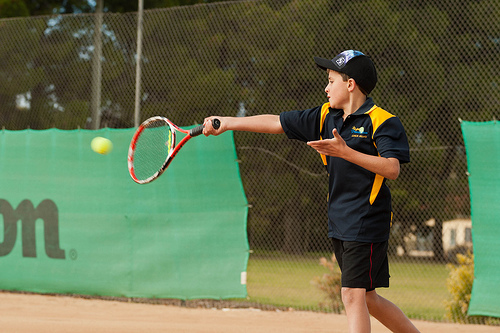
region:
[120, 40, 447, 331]
The boy plays tennis.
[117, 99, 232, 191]
The boy holds a racquet.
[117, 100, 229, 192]
The racquet is red.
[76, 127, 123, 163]
The ball is airborne.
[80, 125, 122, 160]
The ball is yellow.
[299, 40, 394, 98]
The boy wears a cap.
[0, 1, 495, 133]
A chain link fence is behind the court.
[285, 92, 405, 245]
The boy's shirt is yellow and blue.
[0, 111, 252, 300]
A green material is attached to the fence.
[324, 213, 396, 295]
The boy wears black shorts.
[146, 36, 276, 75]
green fence in the background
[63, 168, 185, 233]
green sign on fence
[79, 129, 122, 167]
yellow ball flying in the air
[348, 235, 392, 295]
red stripe on black shorts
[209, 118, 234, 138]
black edge of tennis racket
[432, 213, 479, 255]
white house peeking out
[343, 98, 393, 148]
yellow color on shirt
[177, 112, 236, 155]
black handle on racket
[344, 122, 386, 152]
word on black shirt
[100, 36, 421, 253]
boy hitting the racket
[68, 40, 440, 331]
a boy playing tennis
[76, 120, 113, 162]
a yellow tennis ball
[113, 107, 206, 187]
a red tennis racket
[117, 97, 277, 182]
boy holding a tennis racket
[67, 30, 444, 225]
boy about to hit a tennis ball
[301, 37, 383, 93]
boy wearing a black cap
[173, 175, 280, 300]
green tarp on a metal fence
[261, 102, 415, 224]
boy wearing a dark blue and yellow shirt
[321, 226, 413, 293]
black shorts with a red line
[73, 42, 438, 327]
boy playing tennis in a tennis court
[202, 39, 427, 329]
a young boy on court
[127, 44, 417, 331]
a young boy swinging tennis racket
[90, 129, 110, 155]
a yellow tennis ball in flight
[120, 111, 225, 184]
a red and black tennis racket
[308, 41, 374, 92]
a dark blue hat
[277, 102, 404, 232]
a dark blue and yellow shirt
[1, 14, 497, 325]
a chain link fence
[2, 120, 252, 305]
a long green promotional banner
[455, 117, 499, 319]
a long green promotional banner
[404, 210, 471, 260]
a building in distance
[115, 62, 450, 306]
Boy playing tennis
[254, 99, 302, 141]
Elbow is straight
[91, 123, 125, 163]
Green ball near racket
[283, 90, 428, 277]
Shirt is yellow and black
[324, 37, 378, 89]
Hat is black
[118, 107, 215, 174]
Racket is red and white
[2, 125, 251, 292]
Green fence in background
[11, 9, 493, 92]
Row of trees behind boy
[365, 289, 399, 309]
Boy's right knee is bent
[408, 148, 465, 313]
Fence without covering